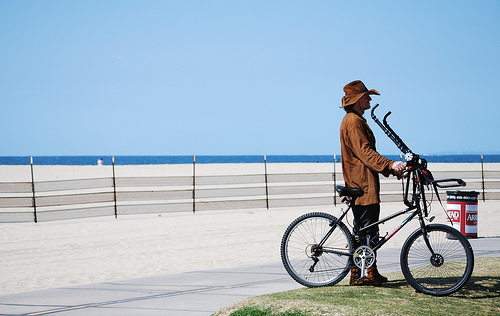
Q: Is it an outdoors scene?
A: Yes, it is outdoors.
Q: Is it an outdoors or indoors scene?
A: It is outdoors.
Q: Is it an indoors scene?
A: No, it is outdoors.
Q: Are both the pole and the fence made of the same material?
A: Yes, both the pole and the fence are made of metal.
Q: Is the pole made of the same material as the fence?
A: Yes, both the pole and the fence are made of metal.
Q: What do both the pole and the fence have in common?
A: The material, both the pole and the fence are metallic.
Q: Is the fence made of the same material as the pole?
A: Yes, both the fence and the pole are made of metal.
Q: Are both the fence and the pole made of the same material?
A: Yes, both the fence and the pole are made of metal.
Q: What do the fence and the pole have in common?
A: The material, both the fence and the pole are metallic.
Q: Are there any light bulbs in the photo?
A: No, there are no light bulbs.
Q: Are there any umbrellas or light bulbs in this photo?
A: No, there are no light bulbs or umbrellas.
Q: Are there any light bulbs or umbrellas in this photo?
A: No, there are no light bulbs or umbrellas.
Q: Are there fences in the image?
A: Yes, there is a fence.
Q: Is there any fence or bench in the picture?
A: Yes, there is a fence.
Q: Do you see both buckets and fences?
A: No, there is a fence but no buckets.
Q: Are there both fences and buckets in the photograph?
A: No, there is a fence but no buckets.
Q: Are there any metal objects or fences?
A: Yes, there is a metal fence.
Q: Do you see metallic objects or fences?
A: Yes, there is a metal fence.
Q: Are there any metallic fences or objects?
A: Yes, there is a metal fence.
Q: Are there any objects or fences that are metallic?
A: Yes, the fence is metallic.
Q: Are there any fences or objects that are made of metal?
A: Yes, the fence is made of metal.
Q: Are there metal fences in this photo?
A: Yes, there is a metal fence.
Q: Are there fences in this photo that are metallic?
A: Yes, there is a fence that is metallic.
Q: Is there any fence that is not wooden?
A: Yes, there is a metallic fence.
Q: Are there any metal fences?
A: Yes, there is a fence that is made of metal.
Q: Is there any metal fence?
A: Yes, there is a fence that is made of metal.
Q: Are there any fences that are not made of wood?
A: Yes, there is a fence that is made of metal.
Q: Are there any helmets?
A: No, there are no helmets.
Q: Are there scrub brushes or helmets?
A: No, there are no helmets or scrub brushes.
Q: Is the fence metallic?
A: Yes, the fence is metallic.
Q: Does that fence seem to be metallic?
A: Yes, the fence is metallic.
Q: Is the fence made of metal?
A: Yes, the fence is made of metal.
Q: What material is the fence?
A: The fence is made of metal.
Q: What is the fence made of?
A: The fence is made of metal.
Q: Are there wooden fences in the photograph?
A: No, there is a fence but it is metallic.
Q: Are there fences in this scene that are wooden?
A: No, there is a fence but it is metallic.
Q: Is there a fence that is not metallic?
A: No, there is a fence but it is metallic.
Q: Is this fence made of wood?
A: No, the fence is made of metal.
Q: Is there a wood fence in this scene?
A: No, there is a fence but it is made of metal.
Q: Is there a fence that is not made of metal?
A: No, there is a fence but it is made of metal.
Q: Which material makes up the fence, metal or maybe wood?
A: The fence is made of metal.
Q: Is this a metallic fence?
A: Yes, this is a metallic fence.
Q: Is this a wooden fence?
A: No, this is a metallic fence.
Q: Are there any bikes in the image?
A: Yes, there is a bike.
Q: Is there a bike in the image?
A: Yes, there is a bike.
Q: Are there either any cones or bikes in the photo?
A: Yes, there is a bike.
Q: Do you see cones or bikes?
A: Yes, there is a bike.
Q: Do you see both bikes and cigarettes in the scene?
A: No, there is a bike but no cigarettes.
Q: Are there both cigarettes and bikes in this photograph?
A: No, there is a bike but no cigarettes.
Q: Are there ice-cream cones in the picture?
A: No, there are no ice-cream cones.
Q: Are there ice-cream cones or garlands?
A: No, there are no ice-cream cones or garlands.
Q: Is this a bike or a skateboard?
A: This is a bike.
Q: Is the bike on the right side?
A: Yes, the bike is on the right of the image.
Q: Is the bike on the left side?
A: No, the bike is on the right of the image.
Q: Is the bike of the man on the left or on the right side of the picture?
A: The bike is on the right of the image.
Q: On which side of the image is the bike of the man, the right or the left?
A: The bike is on the right of the image.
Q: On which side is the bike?
A: The bike is on the right of the image.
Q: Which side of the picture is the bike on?
A: The bike is on the right of the image.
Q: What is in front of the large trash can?
A: The bike is in front of the trashcan.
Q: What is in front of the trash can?
A: The bike is in front of the trashcan.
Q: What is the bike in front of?
A: The bike is in front of the garbage can.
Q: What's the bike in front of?
A: The bike is in front of the garbage can.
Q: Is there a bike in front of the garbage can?
A: Yes, there is a bike in front of the garbage can.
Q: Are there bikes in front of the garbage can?
A: Yes, there is a bike in front of the garbage can.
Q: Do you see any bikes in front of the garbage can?
A: Yes, there is a bike in front of the garbage can.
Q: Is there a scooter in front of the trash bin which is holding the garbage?
A: No, there is a bike in front of the garbage bin.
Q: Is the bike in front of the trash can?
A: Yes, the bike is in front of the trash can.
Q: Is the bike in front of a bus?
A: No, the bike is in front of the trash can.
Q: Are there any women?
A: No, there are no women.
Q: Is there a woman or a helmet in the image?
A: No, there are no women or helmets.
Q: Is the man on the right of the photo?
A: Yes, the man is on the right of the image.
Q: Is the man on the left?
A: No, the man is on the right of the image.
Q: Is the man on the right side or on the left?
A: The man is on the right of the image.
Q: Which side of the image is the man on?
A: The man is on the right of the image.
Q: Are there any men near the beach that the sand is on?
A: Yes, there is a man near the beach.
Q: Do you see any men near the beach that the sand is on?
A: Yes, there is a man near the beach.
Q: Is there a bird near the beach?
A: No, there is a man near the beach.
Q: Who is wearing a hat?
A: The man is wearing a hat.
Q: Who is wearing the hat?
A: The man is wearing a hat.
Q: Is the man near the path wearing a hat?
A: Yes, the man is wearing a hat.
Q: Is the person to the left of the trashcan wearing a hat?
A: Yes, the man is wearing a hat.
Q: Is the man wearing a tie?
A: No, the man is wearing a hat.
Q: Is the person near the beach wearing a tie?
A: No, the man is wearing a hat.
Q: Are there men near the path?
A: Yes, there is a man near the path.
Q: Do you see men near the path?
A: Yes, there is a man near the path.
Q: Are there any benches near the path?
A: No, there is a man near the path.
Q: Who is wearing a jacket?
A: The man is wearing a jacket.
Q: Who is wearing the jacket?
A: The man is wearing a jacket.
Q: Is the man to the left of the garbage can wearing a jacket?
A: Yes, the man is wearing a jacket.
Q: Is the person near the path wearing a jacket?
A: Yes, the man is wearing a jacket.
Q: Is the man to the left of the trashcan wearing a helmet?
A: No, the man is wearing a jacket.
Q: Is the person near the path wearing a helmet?
A: No, the man is wearing a jacket.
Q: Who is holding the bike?
A: The man is holding the bike.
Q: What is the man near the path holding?
A: The man is holding the bike.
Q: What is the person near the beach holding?
A: The man is holding the bike.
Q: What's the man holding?
A: The man is holding the bike.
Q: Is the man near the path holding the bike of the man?
A: Yes, the man is holding the bike.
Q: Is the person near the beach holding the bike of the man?
A: Yes, the man is holding the bike.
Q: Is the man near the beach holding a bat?
A: No, the man is holding the bike.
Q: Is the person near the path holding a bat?
A: No, the man is holding the bike.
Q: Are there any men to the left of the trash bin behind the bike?
A: Yes, there is a man to the left of the trash can.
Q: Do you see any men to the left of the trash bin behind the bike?
A: Yes, there is a man to the left of the trash can.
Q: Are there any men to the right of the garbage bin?
A: No, the man is to the left of the garbage bin.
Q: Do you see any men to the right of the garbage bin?
A: No, the man is to the left of the garbage bin.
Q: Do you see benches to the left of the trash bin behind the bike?
A: No, there is a man to the left of the trashcan.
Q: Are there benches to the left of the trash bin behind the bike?
A: No, there is a man to the left of the trashcan.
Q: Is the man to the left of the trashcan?
A: Yes, the man is to the left of the trashcan.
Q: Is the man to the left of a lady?
A: No, the man is to the left of the trashcan.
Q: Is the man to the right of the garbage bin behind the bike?
A: No, the man is to the left of the trash bin.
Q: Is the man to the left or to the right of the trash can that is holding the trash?
A: The man is to the left of the garbage bin.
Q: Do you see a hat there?
A: Yes, there is a hat.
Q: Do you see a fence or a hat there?
A: Yes, there is a hat.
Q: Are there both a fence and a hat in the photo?
A: Yes, there are both a hat and a fence.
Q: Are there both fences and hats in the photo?
A: Yes, there are both a hat and a fence.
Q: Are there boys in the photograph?
A: No, there are no boys.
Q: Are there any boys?
A: No, there are no boys.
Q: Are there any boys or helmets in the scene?
A: No, there are no boys or helmets.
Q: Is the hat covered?
A: Yes, the hat is covered.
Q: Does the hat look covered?
A: Yes, the hat is covered.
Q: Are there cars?
A: No, there are no cars.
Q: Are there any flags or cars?
A: No, there are no cars or flags.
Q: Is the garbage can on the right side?
A: Yes, the garbage can is on the right of the image.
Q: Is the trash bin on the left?
A: No, the trash bin is on the right of the image.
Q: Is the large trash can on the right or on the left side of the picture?
A: The trash can is on the right of the image.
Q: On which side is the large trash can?
A: The trash bin is on the right of the image.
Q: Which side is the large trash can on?
A: The trash bin is on the right of the image.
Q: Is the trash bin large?
A: Yes, the trash bin is large.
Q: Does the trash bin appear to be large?
A: Yes, the trash bin is large.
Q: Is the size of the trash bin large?
A: Yes, the trash bin is large.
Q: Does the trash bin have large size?
A: Yes, the trash bin is large.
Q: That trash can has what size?
A: The trash can is large.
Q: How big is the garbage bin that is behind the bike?
A: The garbage bin is large.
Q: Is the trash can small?
A: No, the trash can is large.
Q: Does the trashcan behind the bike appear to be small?
A: No, the trash bin is large.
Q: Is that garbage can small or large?
A: The garbage can is large.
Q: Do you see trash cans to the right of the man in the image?
A: Yes, there is a trash can to the right of the man.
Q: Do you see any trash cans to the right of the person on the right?
A: Yes, there is a trash can to the right of the man.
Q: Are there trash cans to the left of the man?
A: No, the trash can is to the right of the man.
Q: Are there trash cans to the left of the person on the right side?
A: No, the trash can is to the right of the man.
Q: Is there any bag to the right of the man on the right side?
A: No, there is a trash can to the right of the man.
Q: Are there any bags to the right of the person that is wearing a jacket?
A: No, there is a trash can to the right of the man.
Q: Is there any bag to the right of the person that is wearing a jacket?
A: No, there is a trash can to the right of the man.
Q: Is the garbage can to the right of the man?
A: Yes, the garbage can is to the right of the man.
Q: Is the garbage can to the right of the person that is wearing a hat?
A: Yes, the garbage can is to the right of the man.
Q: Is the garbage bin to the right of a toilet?
A: No, the garbage bin is to the right of the man.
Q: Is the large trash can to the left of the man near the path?
A: No, the garbage can is to the right of the man.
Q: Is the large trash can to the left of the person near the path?
A: No, the garbage can is to the right of the man.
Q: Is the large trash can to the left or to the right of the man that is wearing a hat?
A: The garbage can is to the right of the man.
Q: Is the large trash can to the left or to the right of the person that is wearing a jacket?
A: The garbage can is to the right of the man.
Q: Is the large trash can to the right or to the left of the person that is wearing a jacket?
A: The garbage can is to the right of the man.